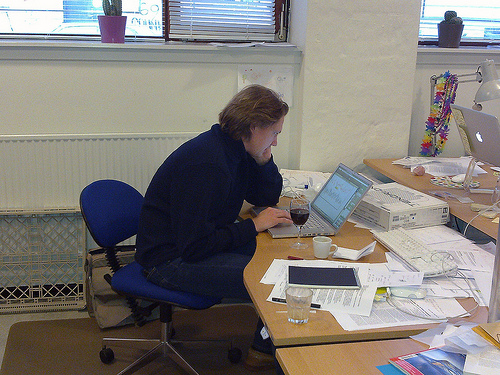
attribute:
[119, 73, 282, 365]
man — working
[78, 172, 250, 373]
chair — blue, royal blue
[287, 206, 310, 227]
wine — red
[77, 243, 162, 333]
bag — beige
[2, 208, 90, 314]
baby gate — white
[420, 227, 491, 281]
paper — white, scattered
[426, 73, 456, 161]
necklace — flowers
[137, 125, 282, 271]
sweater — blue, dark, pullover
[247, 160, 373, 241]
laptop — silver, on, open, gray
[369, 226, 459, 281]
keyboard — white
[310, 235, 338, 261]
cup — glass, empty, white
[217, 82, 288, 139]
hair — brown, dark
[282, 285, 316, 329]
glass — small, clear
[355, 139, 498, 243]
table — brown, wooden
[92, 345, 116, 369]
wheel — black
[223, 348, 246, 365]
wheel — black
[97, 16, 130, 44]
pot — pink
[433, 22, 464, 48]
pot — brown